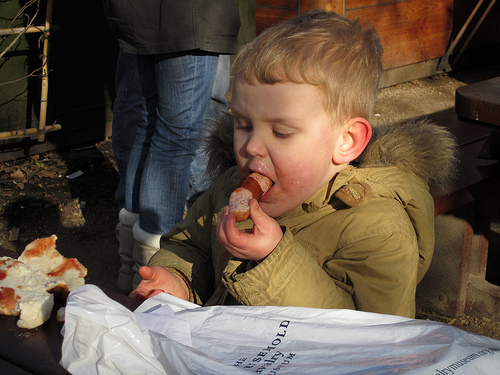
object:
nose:
[245, 132, 267, 157]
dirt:
[9, 137, 67, 211]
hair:
[232, 9, 388, 131]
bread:
[0, 234, 90, 330]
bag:
[134, 292, 500, 374]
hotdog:
[228, 171, 274, 222]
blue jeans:
[108, 48, 220, 234]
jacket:
[147, 107, 456, 319]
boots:
[117, 208, 136, 293]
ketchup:
[47, 258, 81, 276]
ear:
[332, 116, 374, 165]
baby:
[128, 8, 460, 318]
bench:
[471, 131, 500, 227]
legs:
[133, 18, 220, 272]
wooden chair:
[415, 214, 500, 321]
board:
[384, 19, 416, 64]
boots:
[132, 220, 162, 290]